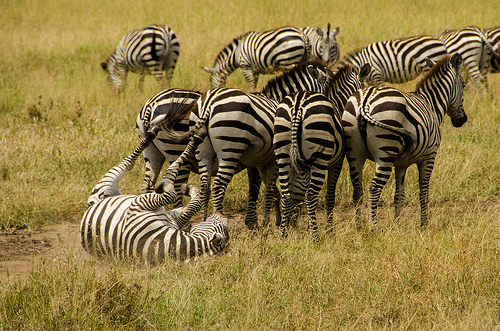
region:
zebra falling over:
[48, 99, 237, 276]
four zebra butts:
[94, 82, 458, 182]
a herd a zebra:
[78, 16, 498, 244]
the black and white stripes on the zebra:
[250, 81, 353, 171]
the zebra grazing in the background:
[60, 21, 198, 104]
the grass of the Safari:
[199, 221, 499, 301]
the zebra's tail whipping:
[60, 93, 205, 206]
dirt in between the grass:
[4, 191, 102, 300]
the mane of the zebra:
[388, 42, 472, 106]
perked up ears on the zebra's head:
[307, 21, 360, 42]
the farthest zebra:
[97, 20, 192, 106]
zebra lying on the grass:
[75, 123, 239, 271]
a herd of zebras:
[77, 16, 497, 271]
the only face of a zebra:
[312, 17, 347, 70]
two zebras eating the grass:
[94, 8, 309, 113]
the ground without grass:
[0, 190, 107, 305]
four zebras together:
[132, 57, 475, 232]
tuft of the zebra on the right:
[404, 46, 456, 105]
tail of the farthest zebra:
[140, 21, 162, 73]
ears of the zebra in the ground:
[205, 229, 228, 271]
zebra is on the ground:
[75, 125, 266, 286]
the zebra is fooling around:
[52, 91, 224, 303]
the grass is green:
[208, 232, 345, 318]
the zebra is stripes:
[69, 133, 275, 310]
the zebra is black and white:
[88, 115, 266, 280]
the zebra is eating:
[75, 19, 225, 122]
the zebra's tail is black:
[142, 89, 202, 145]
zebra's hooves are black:
[133, 121, 215, 143]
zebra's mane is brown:
[406, 51, 449, 105]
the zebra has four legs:
[74, 108, 254, 238]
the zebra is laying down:
[37, 145, 284, 330]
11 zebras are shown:
[27, 15, 492, 315]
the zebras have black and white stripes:
[41, 15, 491, 285]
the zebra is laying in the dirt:
[27, 147, 222, 304]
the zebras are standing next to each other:
[135, 80, 495, 225]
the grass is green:
[28, 247, 357, 319]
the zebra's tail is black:
[119, 21, 189, 93]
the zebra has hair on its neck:
[391, 40, 495, 142]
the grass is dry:
[231, 236, 458, 321]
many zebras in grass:
[68, 19, 464, 302]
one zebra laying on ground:
[25, 126, 298, 273]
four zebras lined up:
[99, 11, 493, 277]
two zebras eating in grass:
[54, 39, 336, 102]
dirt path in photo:
[0, 141, 497, 287]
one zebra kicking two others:
[39, 91, 267, 311]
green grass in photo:
[4, 41, 429, 310]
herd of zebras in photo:
[96, 24, 498, 226]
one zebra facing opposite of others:
[281, 11, 373, 95]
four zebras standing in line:
[67, 14, 485, 269]